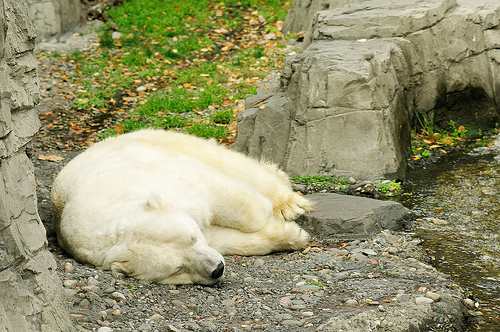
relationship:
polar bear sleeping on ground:
[57, 128, 313, 285] [7, 3, 495, 331]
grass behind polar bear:
[38, 3, 306, 152] [57, 128, 313, 285]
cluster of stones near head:
[2, 3, 74, 329] [113, 196, 226, 290]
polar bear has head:
[57, 128, 313, 285] [113, 196, 226, 290]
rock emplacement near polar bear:
[239, 6, 497, 201] [57, 128, 313, 285]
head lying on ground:
[113, 196, 226, 290] [7, 3, 495, 331]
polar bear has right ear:
[57, 128, 313, 285] [107, 256, 135, 279]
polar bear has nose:
[57, 128, 313, 285] [210, 258, 230, 280]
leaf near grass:
[117, 49, 131, 65] [38, 3, 306, 152]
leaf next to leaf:
[170, 34, 182, 44] [169, 47, 180, 57]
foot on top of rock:
[273, 192, 314, 223] [290, 190, 412, 248]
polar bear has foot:
[57, 128, 313, 285] [273, 192, 314, 223]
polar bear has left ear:
[57, 128, 313, 285] [141, 194, 166, 211]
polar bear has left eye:
[57, 128, 313, 285] [183, 233, 199, 248]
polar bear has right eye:
[57, 128, 313, 285] [173, 262, 187, 276]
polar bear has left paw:
[57, 128, 313, 285] [244, 195, 270, 230]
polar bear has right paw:
[57, 128, 313, 285] [268, 218, 307, 254]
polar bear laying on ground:
[57, 128, 313, 285] [7, 3, 495, 331]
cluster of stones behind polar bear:
[2, 3, 74, 329] [57, 128, 313, 285]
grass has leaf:
[38, 3, 306, 152] [117, 49, 131, 65]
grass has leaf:
[38, 3, 306, 152] [142, 56, 158, 65]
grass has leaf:
[38, 3, 306, 152] [169, 47, 180, 57]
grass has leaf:
[38, 3, 306, 152] [170, 34, 182, 44]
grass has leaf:
[38, 3, 306, 152] [221, 40, 235, 56]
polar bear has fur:
[57, 128, 313, 285] [55, 124, 307, 283]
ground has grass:
[7, 3, 495, 331] [38, 3, 306, 152]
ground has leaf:
[7, 3, 495, 331] [117, 49, 131, 65]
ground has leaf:
[7, 3, 495, 331] [142, 56, 158, 65]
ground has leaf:
[7, 3, 495, 331] [169, 47, 180, 57]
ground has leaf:
[7, 3, 495, 331] [170, 34, 182, 44]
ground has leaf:
[7, 3, 495, 331] [221, 40, 235, 56]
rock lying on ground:
[290, 190, 412, 248] [7, 3, 495, 331]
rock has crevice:
[239, 6, 497, 201] [393, 84, 494, 178]